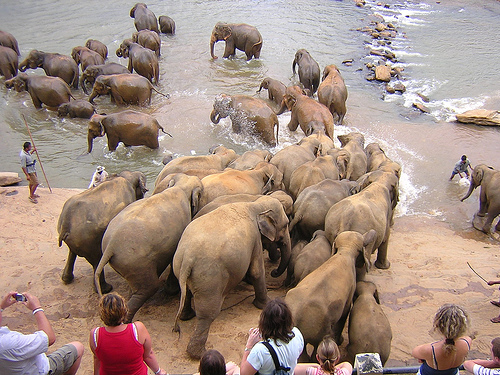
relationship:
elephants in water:
[3, 2, 354, 149] [3, 1, 498, 193]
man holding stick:
[20, 142, 41, 204] [23, 124, 35, 143]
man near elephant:
[20, 142, 41, 204] [73, 177, 113, 222]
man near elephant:
[20, 142, 41, 204] [107, 112, 152, 143]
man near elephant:
[20, 142, 41, 204] [163, 148, 217, 175]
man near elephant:
[20, 142, 41, 204] [126, 197, 172, 247]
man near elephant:
[20, 142, 41, 204] [56, 99, 96, 124]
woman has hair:
[412, 304, 473, 375] [431, 307, 465, 340]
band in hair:
[439, 307, 457, 311] [431, 307, 465, 340]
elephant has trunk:
[209, 21, 264, 59] [209, 38, 216, 64]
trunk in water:
[209, 38, 216, 64] [193, 10, 362, 69]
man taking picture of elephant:
[0, 287, 88, 373] [207, 19, 264, 64]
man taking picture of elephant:
[0, 287, 88, 373] [169, 199, 293, 351]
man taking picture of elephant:
[0, 287, 88, 373] [294, 229, 330, 279]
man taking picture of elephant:
[0, 287, 88, 373] [347, 277, 395, 369]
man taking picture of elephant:
[0, 287, 88, 373] [79, 110, 171, 153]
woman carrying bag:
[238, 297, 304, 374] [245, 336, 293, 374]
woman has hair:
[412, 303, 487, 374] [433, 306, 470, 337]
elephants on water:
[3, 2, 354, 149] [3, 1, 498, 193]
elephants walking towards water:
[460, 164, 500, 233] [1, 0, 494, 213]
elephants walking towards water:
[54, 47, 499, 369] [1, 1, 497, 245]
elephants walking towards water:
[64, 140, 377, 309] [273, 10, 404, 77]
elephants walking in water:
[60, 126, 406, 337] [336, 112, 459, 205]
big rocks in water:
[361, 25, 408, 90] [1, 0, 494, 213]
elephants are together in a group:
[103, 158, 386, 294] [65, 141, 473, 294]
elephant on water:
[6, 3, 496, 363] [440, 157, 495, 203]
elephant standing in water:
[207, 19, 264, 64] [1, 0, 494, 213]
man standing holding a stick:
[14, 123, 57, 193] [14, 109, 78, 206]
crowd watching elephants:
[0, 289, 499, 374] [13, 270, 465, 344]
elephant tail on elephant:
[170, 248, 194, 333] [172, 194, 292, 360]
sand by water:
[373, 233, 497, 348] [3, 1, 498, 193]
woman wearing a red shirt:
[87, 287, 167, 372] [92, 324, 154, 374]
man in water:
[446, 152, 476, 179] [353, 110, 473, 165]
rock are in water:
[374, 61, 391, 84] [1, 1, 497, 245]